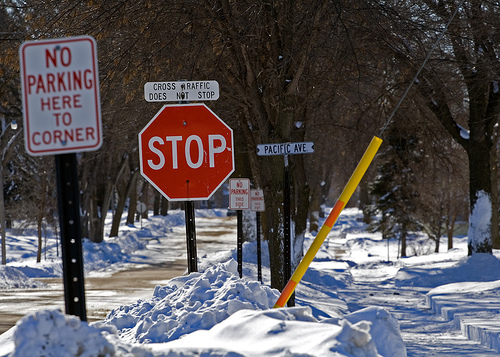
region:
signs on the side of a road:
[20, 23, 370, 353]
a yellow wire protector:
[239, 77, 436, 322]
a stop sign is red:
[111, 28, 292, 276]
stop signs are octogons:
[116, 45, 250, 250]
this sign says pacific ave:
[236, 125, 330, 172]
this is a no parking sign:
[17, 26, 159, 221]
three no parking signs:
[25, 13, 338, 330]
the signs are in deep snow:
[23, 15, 382, 351]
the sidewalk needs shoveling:
[324, 236, 479, 353]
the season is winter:
[27, 25, 496, 309]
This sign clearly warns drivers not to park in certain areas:
[17, 40, 100, 152]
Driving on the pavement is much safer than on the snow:
[90, 244, 183, 299]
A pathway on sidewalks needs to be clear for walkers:
[391, 295, 460, 341]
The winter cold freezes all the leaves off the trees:
[4, 172, 53, 216]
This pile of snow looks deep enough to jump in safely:
[131, 280, 264, 336]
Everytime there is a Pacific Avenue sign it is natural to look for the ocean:
[256, 138, 313, 159]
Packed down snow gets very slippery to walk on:
[407, 333, 463, 349]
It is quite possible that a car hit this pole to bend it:
[291, 136, 383, 303]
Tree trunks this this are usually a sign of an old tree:
[466, 24, 497, 245]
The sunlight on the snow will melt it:
[342, 231, 374, 267]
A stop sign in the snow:
[140, 103, 235, 270]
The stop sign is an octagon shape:
[137, 102, 237, 200]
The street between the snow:
[0, 210, 248, 327]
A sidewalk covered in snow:
[338, 215, 490, 355]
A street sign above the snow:
[259, 143, 316, 304]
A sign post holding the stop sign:
[183, 200, 199, 272]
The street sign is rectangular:
[261, 140, 315, 152]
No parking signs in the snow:
[228, 178, 267, 280]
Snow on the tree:
[466, 193, 493, 248]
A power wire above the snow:
[271, 2, 463, 306]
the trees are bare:
[0, 0, 499, 292]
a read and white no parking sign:
[14, 31, 106, 160]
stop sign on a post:
[133, 103, 238, 276]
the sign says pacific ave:
[253, 139, 316, 157]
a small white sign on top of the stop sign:
[140, 77, 221, 104]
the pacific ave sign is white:
[254, 139, 316, 157]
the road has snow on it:
[0, 209, 243, 354]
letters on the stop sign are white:
[135, 102, 235, 202]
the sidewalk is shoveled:
[328, 227, 498, 354]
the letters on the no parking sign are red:
[17, 32, 104, 155]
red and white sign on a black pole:
[15, 35, 103, 328]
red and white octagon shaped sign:
[138, 102, 235, 201]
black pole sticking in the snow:
[183, 202, 196, 270]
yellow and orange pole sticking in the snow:
[275, 135, 380, 305]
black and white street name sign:
[255, 138, 312, 154]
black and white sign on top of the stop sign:
[142, 77, 218, 98]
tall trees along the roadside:
[0, 0, 182, 267]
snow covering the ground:
[1, 190, 496, 350]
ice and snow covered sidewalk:
[340, 231, 496, 352]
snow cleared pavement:
[84, 255, 189, 291]